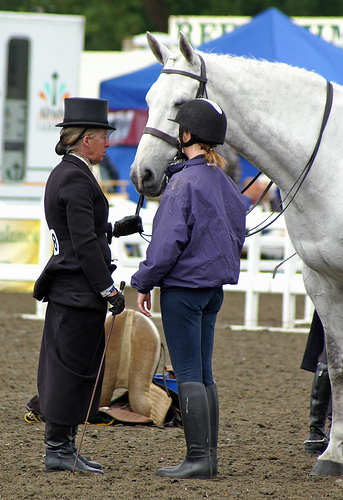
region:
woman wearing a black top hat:
[54, 98, 115, 128]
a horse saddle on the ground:
[99, 308, 177, 428]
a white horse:
[129, 29, 337, 481]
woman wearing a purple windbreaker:
[134, 156, 245, 293]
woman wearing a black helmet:
[168, 97, 226, 152]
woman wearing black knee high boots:
[157, 383, 219, 480]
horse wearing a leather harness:
[141, 51, 207, 166]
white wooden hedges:
[24, 196, 311, 332]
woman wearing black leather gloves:
[105, 213, 144, 317]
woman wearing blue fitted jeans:
[162, 287, 222, 384]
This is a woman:
[24, 88, 128, 495]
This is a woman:
[130, 92, 245, 492]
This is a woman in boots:
[25, 83, 126, 486]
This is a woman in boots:
[131, 93, 243, 492]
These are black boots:
[149, 370, 239, 493]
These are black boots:
[28, 403, 127, 492]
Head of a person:
[43, 91, 122, 178]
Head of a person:
[161, 73, 234, 171]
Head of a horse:
[115, 28, 290, 208]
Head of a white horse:
[114, 22, 267, 214]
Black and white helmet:
[164, 95, 228, 147]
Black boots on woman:
[146, 371, 242, 484]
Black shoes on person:
[31, 434, 108, 484]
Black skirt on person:
[29, 286, 109, 433]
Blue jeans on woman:
[155, 277, 228, 389]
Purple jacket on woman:
[122, 156, 253, 298]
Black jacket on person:
[28, 153, 116, 312]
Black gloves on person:
[104, 211, 149, 321]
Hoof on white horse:
[304, 454, 342, 482]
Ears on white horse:
[137, 26, 209, 69]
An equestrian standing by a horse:
[129, 96, 248, 483]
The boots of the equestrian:
[153, 377, 217, 480]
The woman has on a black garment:
[20, 84, 135, 476]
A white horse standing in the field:
[132, 27, 337, 480]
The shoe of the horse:
[304, 453, 338, 475]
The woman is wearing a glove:
[103, 285, 124, 311]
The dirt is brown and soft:
[108, 441, 308, 491]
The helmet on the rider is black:
[166, 98, 227, 154]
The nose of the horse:
[126, 165, 160, 190]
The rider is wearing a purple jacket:
[129, 154, 243, 289]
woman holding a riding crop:
[34, 98, 117, 475]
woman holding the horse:
[35, 95, 143, 483]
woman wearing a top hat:
[33, 97, 142, 473]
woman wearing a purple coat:
[129, 99, 248, 477]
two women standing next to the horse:
[30, 96, 249, 480]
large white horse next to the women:
[129, 30, 342, 478]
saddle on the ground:
[96, 310, 178, 427]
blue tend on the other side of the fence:
[99, 9, 342, 201]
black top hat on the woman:
[52, 95, 115, 131]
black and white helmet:
[167, 97, 227, 143]